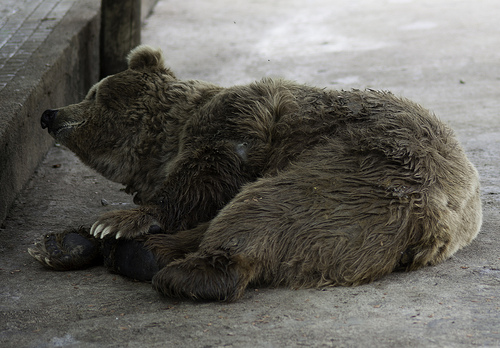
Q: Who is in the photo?
A: Nobody.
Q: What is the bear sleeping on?
A: The ground.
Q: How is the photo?
A: Clear.